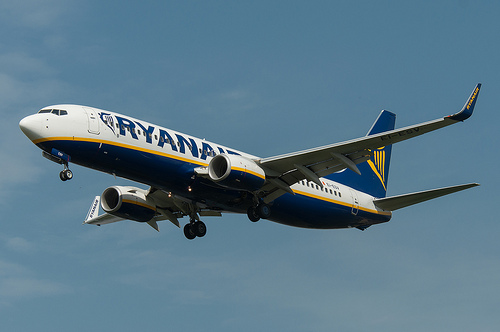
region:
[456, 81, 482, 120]
winglet that increases fuel efficiency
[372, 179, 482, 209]
horizontal stabilizer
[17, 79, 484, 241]
Ryanair Jet Airplane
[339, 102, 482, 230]
tail section of airplane with vertical and horizontal stabilizers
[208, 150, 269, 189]
Jet engine painted in Ryanair white, blue and yellow colors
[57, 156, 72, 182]
airplane front landing gear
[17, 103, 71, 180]
nose section of airplane with cockpit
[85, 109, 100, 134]
airplane entry door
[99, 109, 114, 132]
Ryanair logo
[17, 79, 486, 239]
Jet airplane decorated in the Ryanair color scheme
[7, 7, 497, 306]
The sky is clear blue.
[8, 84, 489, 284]
The plane is in the air.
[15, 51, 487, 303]
The plane is flying.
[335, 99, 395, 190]
The tail is blue and yellow.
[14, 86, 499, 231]
The plane is white.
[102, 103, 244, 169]
The lettering is blue.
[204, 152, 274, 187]
The jet is white, blue, and yellow.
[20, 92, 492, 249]
The plane is large.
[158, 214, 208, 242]
The tires are out.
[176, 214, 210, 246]
The tires are black.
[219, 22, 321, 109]
this is the sky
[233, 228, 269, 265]
the sky is blue in color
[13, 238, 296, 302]
the sky has clouds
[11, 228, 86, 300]
the clouds are white in color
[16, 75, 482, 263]
this is an airplane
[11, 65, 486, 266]
the airplane is big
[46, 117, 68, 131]
the airplane is white in color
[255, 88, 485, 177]
this is a wing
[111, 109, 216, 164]
these are some writings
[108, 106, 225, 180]
the writings are in bold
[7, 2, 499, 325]
blue of daytime sky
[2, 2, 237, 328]
thin white clouds in sky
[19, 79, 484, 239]
jet plane in flight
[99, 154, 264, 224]
two cylinder shaped engines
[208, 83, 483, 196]
jet engine under wing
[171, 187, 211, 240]
wheels on landing gear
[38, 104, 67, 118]
windows on plane cockpit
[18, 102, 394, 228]
white top of plane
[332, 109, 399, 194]
blue and yellow tail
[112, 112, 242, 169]
blue word on white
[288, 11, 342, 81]
part of the sky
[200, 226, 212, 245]
part of a wheel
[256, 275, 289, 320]
part of the sku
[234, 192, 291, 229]
part of a wheel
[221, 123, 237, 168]
part of an engine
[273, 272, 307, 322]
part of a cloud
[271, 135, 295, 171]
edge of a wing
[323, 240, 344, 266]
part of a cloud